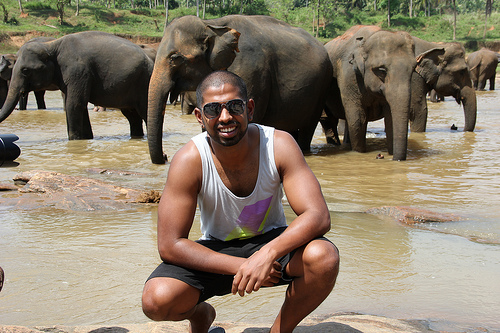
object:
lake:
[0, 51, 500, 330]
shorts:
[143, 230, 346, 303]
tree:
[381, 0, 397, 32]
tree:
[447, 1, 461, 41]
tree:
[480, 0, 494, 42]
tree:
[147, 1, 169, 35]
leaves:
[382, 13, 429, 29]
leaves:
[314, 19, 345, 39]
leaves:
[211, 1, 271, 14]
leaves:
[27, 1, 62, 17]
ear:
[169, 23, 241, 72]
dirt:
[143, 60, 174, 131]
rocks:
[358, 194, 497, 230]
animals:
[0, 13, 499, 165]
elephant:
[320, 23, 415, 160]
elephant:
[408, 41, 476, 134]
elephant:
[142, 12, 334, 167]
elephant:
[464, 47, 497, 92]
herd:
[0, 7, 499, 167]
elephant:
[1, 29, 153, 141]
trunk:
[146, 72, 168, 167]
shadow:
[243, 322, 364, 332]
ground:
[0, 1, 500, 75]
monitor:
[1, 13, 498, 163]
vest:
[190, 124, 288, 242]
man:
[140, 71, 341, 333]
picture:
[0, 1, 384, 237]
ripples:
[340, 163, 493, 205]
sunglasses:
[199, 97, 247, 121]